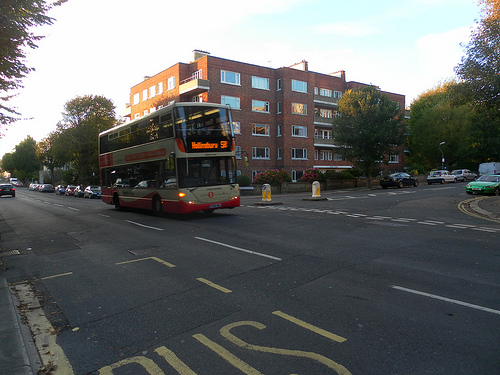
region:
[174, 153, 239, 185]
Front windshield on a bus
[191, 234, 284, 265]
White line painted on the street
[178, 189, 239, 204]
Headlights on a bus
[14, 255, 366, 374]
Yellow paint on the street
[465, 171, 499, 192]
Green car parked on the street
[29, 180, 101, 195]
Cars parked on the side of street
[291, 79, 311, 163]
Windows on the side of a building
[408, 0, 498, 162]
Green leaves in the trees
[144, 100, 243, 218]
Front end of a double-deck bus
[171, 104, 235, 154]
Front window of a double-deck bus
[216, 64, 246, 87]
The window is rectangular.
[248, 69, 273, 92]
The window is rectangular.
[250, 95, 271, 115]
The window is rectangular.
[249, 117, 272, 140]
The window is rectangular.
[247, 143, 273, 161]
The window is rectangular.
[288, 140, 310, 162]
The window is rectangular.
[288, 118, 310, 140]
The window is rectangular.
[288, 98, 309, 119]
The window is rectangular.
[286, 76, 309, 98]
The window is rectangular.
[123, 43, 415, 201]
The building is brick.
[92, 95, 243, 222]
A red and beige bus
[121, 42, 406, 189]
A large brown building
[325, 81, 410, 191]
Green leaves are on a tree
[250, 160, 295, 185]
Pink flowers in a bush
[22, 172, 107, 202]
Cars are parked on side of a road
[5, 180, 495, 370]
White and yellow lines on the road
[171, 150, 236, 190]
A front window of a bus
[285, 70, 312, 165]
Four windows on side of the building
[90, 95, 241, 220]
The bus is double decker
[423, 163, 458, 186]
A car is white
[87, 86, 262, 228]
a bus with two levels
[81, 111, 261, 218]
a white and red bus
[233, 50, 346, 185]
a red apartment building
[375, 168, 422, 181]
a black car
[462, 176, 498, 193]
a green car parked by a corner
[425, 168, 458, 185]
a silver sedan parked on the street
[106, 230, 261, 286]
asphalt with yellow and white markings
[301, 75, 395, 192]
a tree growing in front of a building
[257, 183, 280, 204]
a grey and orange trash can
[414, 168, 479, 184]
a silver car parked behind another silver car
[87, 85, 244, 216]
double deck bus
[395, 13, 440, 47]
white clouds in blue sky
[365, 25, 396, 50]
white clouds in blue sky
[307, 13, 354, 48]
white clouds in blue sky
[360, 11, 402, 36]
white clouds in blue sky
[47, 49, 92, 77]
white clouds in blue sky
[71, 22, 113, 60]
white clouds in blue sky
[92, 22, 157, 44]
white clouds in blue sky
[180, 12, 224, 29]
white clouds in blue sky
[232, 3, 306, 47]
white clouds in blue sky